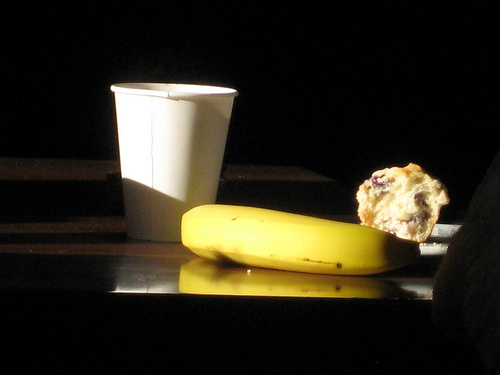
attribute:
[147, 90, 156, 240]
seam — white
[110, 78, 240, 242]
cup — white, paper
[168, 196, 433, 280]
banana — yellow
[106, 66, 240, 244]
cup — white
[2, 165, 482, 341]
table — wood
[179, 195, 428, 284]
banana — yellow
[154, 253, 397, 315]
reflection — banana's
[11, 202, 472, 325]
surface — table's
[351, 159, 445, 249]
muffin — eaten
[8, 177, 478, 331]
table — dark brown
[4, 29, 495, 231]
background — black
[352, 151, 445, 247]
muffin — blueberry 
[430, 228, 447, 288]
plate — white 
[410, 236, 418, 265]
banana — stem 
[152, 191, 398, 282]
banana — brown, spotted